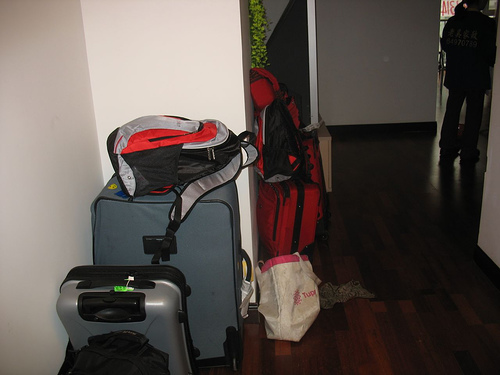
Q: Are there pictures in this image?
A: No, there are no pictures.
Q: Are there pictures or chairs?
A: No, there are no pictures or chairs.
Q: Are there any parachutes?
A: No, there are no parachutes.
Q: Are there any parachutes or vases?
A: No, there are no parachutes or vases.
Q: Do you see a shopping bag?
A: Yes, there is a shopping bag.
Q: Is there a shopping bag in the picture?
A: Yes, there is a shopping bag.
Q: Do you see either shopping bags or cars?
A: Yes, there is a shopping bag.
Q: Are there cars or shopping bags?
A: Yes, there is a shopping bag.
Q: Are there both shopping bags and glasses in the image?
A: No, there is a shopping bag but no glasses.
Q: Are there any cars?
A: No, there are no cars.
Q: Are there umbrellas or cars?
A: No, there are no cars or umbrellas.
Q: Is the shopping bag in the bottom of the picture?
A: Yes, the shopping bag is in the bottom of the image.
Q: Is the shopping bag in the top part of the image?
A: No, the shopping bag is in the bottom of the image.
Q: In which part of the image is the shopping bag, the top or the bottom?
A: The shopping bag is in the bottom of the image.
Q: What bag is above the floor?
A: The bag is a shopping bag.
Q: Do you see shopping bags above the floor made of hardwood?
A: Yes, there is a shopping bag above the floor.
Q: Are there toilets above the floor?
A: No, there is a shopping bag above the floor.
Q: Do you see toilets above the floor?
A: No, there is a shopping bag above the floor.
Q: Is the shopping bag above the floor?
A: Yes, the shopping bag is above the floor.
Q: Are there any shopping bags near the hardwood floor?
A: Yes, there is a shopping bag near the floor.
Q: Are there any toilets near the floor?
A: No, there is a shopping bag near the floor.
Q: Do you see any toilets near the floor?
A: No, there is a shopping bag near the floor.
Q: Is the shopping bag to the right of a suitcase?
A: Yes, the shopping bag is to the right of a suitcase.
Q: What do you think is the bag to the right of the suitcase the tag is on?
A: The bag is a shopping bag.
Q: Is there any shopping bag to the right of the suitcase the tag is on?
A: Yes, there is a shopping bag to the right of the suitcase.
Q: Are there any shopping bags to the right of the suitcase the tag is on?
A: Yes, there is a shopping bag to the right of the suitcase.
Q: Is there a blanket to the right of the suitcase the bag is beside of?
A: No, there is a shopping bag to the right of the suitcase.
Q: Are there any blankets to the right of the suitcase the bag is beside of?
A: No, there is a shopping bag to the right of the suitcase.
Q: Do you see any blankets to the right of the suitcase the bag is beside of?
A: No, there is a shopping bag to the right of the suitcase.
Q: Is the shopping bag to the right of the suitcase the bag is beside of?
A: Yes, the shopping bag is to the right of the suitcase.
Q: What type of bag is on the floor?
A: The bag is a shopping bag.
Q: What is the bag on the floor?
A: The bag is a shopping bag.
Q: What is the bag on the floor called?
A: The bag is a shopping bag.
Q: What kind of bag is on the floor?
A: The bag is a shopping bag.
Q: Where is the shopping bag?
A: The shopping bag is on the floor.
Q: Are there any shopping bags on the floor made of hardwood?
A: Yes, there is a shopping bag on the floor.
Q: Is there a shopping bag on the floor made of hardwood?
A: Yes, there is a shopping bag on the floor.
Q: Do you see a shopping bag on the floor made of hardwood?
A: Yes, there is a shopping bag on the floor.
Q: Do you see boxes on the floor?
A: No, there is a shopping bag on the floor.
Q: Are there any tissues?
A: No, there are no tissues.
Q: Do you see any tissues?
A: No, there are no tissues.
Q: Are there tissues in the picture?
A: No, there are no tissues.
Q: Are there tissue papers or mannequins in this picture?
A: No, there are no tissue papers or mannequins.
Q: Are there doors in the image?
A: Yes, there is a door.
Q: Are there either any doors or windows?
A: Yes, there is a door.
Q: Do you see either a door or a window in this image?
A: Yes, there is a door.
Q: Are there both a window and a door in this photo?
A: No, there is a door but no windows.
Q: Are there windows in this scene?
A: No, there are no windows.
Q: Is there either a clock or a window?
A: No, there are no windows or clocks.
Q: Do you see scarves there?
A: Yes, there is a scarf.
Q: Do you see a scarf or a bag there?
A: Yes, there is a scarf.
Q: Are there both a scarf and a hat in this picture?
A: No, there is a scarf but no hats.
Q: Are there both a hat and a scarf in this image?
A: No, there is a scarf but no hats.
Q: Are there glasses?
A: No, there are no glasses.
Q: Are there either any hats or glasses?
A: No, there are no glasses or hats.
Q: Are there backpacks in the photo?
A: Yes, there is a backpack.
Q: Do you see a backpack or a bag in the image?
A: Yes, there is a backpack.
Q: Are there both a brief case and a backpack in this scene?
A: No, there is a backpack but no briefcases.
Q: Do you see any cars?
A: No, there are no cars.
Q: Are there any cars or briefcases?
A: No, there are no cars or briefcases.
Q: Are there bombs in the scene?
A: No, there are no bombs.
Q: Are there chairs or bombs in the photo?
A: No, there are no bombs or chairs.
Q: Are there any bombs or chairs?
A: No, there are no bombs or chairs.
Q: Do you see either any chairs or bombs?
A: No, there are no bombs or chairs.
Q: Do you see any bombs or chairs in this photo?
A: No, there are no bombs or chairs.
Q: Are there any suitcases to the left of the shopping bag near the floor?
A: Yes, there is a suitcase to the left of the shopping bag.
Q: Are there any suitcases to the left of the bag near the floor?
A: Yes, there is a suitcase to the left of the shopping bag.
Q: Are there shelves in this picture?
A: No, there are no shelves.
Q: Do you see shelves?
A: No, there are no shelves.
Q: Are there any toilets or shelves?
A: No, there are no shelves or toilets.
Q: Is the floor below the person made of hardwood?
A: Yes, the floor is made of hardwood.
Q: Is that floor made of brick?
A: No, the floor is made of hardwood.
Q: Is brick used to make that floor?
A: No, the floor is made of hardwood.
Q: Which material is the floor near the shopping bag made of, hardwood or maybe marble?
A: The floor is made of hardwood.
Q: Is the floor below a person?
A: Yes, the floor is below a person.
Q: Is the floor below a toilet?
A: No, the floor is below a person.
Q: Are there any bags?
A: Yes, there is a bag.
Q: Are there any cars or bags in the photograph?
A: Yes, there is a bag.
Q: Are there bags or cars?
A: Yes, there is a bag.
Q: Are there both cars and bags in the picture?
A: No, there is a bag but no cars.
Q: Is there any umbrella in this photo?
A: No, there are no umbrellas.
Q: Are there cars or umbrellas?
A: No, there are no umbrellas or cars.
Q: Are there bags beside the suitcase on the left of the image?
A: Yes, there is a bag beside the suitcase.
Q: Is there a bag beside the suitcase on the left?
A: Yes, there is a bag beside the suitcase.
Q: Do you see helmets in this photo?
A: No, there are no helmets.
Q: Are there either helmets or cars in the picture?
A: No, there are no helmets or cars.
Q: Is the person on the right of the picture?
A: Yes, the person is on the right of the image.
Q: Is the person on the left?
A: No, the person is on the right of the image.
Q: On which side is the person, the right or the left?
A: The person is on the right of the image.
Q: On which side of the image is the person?
A: The person is on the right of the image.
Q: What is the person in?
A: The person is in the doorway.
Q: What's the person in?
A: The person is in the doorway.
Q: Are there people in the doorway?
A: Yes, there is a person in the doorway.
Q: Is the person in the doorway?
A: Yes, the person is in the doorway.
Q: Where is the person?
A: The person is on the floor.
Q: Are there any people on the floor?
A: Yes, there is a person on the floor.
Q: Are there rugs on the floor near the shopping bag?
A: No, there is a person on the floor.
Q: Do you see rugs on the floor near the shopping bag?
A: No, there is a person on the floor.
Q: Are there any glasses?
A: No, there are no glasses.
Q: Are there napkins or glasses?
A: No, there are no glasses or napkins.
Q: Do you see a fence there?
A: No, there are no fences.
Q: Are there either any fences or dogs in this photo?
A: No, there are no fences or dogs.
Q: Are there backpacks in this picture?
A: Yes, there is a backpack.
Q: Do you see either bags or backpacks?
A: Yes, there is a backpack.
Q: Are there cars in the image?
A: No, there are no cars.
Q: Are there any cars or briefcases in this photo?
A: No, there are no cars or briefcases.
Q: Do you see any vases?
A: No, there are no vases.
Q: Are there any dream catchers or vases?
A: No, there are no vases or dream catchers.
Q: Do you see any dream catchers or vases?
A: No, there are no vases or dream catchers.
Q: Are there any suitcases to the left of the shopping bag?
A: Yes, there is a suitcase to the left of the shopping bag.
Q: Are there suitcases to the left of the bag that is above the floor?
A: Yes, there is a suitcase to the left of the shopping bag.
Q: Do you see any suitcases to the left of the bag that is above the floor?
A: Yes, there is a suitcase to the left of the shopping bag.